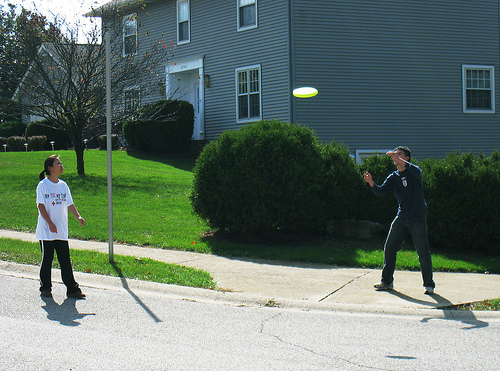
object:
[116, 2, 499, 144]
house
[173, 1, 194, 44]
window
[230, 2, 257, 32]
window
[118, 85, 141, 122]
window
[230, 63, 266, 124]
window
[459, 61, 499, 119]
window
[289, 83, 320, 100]
frisbee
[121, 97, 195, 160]
hedge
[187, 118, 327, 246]
hedge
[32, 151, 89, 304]
girl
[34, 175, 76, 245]
shirt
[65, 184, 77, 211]
sleeve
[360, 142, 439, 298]
boy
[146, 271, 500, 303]
sidewalk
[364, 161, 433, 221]
shirt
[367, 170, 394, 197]
sleeve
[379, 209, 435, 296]
pants